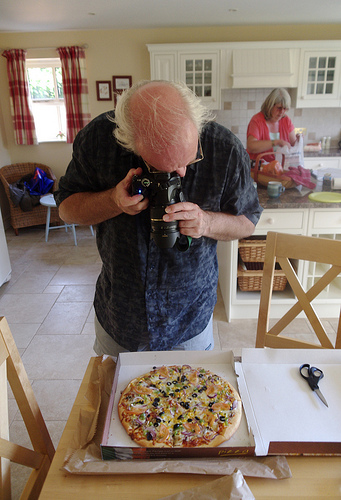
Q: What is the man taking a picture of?
A: Pizza.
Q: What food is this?
A: Pizza.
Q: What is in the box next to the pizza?
A: Scissors.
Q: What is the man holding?
A: Camera.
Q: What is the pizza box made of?
A: Cardboard.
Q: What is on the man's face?
A: Glasses.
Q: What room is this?
A: Kitchen.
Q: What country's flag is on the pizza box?
A: Italy.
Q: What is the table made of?
A: Wood.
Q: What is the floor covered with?
A: Tile.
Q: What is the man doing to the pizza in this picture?
A: Taking a picture of it.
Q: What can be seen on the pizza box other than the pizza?
A: Scissors.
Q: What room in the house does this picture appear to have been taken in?
A: The kitchen.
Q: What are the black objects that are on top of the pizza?
A: Olives.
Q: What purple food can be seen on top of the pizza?
A: Onions.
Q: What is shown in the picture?
A: A kitchen.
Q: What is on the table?
A: A pizza.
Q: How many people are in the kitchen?
A: Two.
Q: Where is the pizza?
A: On a table.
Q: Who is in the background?
A: A woman.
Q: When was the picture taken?
A: In the day.